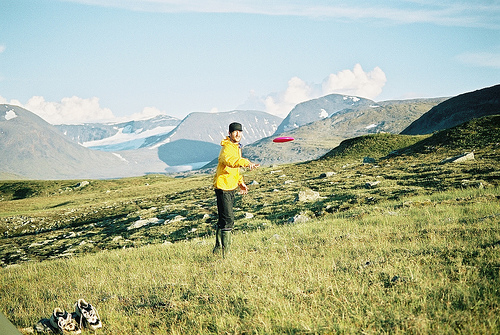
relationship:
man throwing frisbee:
[212, 121, 261, 261] [271, 134, 295, 144]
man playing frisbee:
[212, 121, 261, 261] [271, 134, 295, 144]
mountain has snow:
[1, 102, 103, 179] [4, 108, 19, 124]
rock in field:
[295, 184, 321, 207] [2, 170, 498, 333]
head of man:
[228, 120, 242, 144] [212, 121, 261, 261]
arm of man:
[221, 147, 251, 170] [212, 121, 261, 261]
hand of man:
[244, 160, 260, 172] [212, 121, 261, 261]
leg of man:
[216, 191, 236, 253] [212, 121, 261, 261]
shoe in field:
[75, 296, 104, 330] [2, 170, 498, 333]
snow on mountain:
[4, 108, 19, 124] [1, 102, 103, 179]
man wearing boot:
[212, 121, 261, 261] [221, 228, 234, 262]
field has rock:
[2, 170, 498, 333] [295, 184, 321, 207]